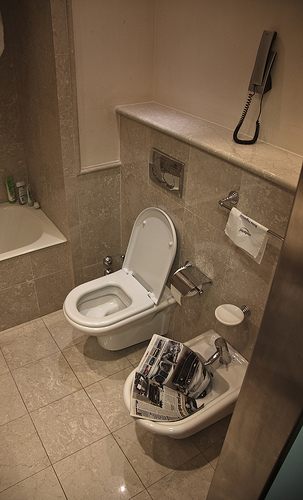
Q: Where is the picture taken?
A: Bathroom.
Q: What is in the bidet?
A: Magazine.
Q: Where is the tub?
A: On the left.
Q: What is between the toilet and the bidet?
A: Toilet paper.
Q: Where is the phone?
A: On the wall.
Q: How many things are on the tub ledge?
A: 4.